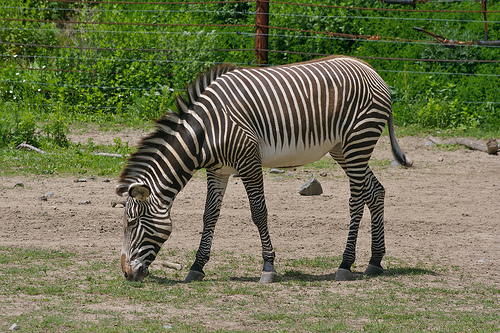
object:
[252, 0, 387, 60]
leaves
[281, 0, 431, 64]
leaves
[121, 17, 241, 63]
leaves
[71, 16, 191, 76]
leaves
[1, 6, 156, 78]
leaves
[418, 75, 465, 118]
leaves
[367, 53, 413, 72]
leaves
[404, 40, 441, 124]
leaves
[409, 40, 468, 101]
leaves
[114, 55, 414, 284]
zebra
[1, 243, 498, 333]
grass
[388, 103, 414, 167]
tail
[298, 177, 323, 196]
rock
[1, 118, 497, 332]
ground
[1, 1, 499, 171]
bush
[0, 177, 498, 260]
dirt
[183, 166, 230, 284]
leg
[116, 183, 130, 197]
ear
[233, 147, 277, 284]
left front leg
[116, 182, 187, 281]
head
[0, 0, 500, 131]
fence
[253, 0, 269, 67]
metal post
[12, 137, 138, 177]
branch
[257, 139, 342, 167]
stomach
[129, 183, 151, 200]
left ear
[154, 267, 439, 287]
shadow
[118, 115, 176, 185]
neck hair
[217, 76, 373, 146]
stripes